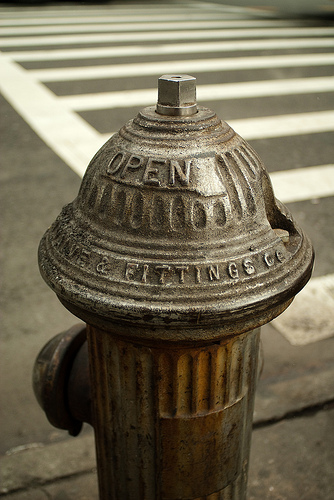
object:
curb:
[2, 366, 331, 495]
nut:
[156, 72, 198, 108]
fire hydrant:
[32, 72, 315, 500]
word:
[169, 159, 192, 185]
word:
[242, 257, 257, 275]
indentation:
[113, 187, 125, 223]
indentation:
[130, 192, 144, 230]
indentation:
[151, 195, 165, 227]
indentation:
[169, 196, 186, 231]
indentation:
[191, 200, 207, 231]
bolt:
[273, 227, 291, 243]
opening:
[262, 180, 300, 253]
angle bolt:
[156, 72, 197, 117]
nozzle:
[32, 321, 92, 437]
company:
[53, 241, 289, 285]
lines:
[0, 16, 327, 35]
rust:
[157, 361, 226, 473]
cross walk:
[0, 0, 333, 346]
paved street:
[0, 2, 333, 498]